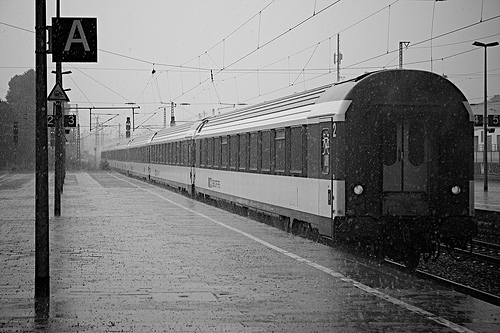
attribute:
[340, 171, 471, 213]
headlight — round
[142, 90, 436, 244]
train — domed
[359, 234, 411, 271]
rain — splashing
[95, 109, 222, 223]
train — domed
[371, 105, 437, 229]
doors — rear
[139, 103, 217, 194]
train — passing through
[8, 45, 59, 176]
trees — distant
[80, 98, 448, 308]
photo — black and white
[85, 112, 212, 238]
train — long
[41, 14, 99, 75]
letter a — suspended, on pole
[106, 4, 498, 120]
wiring — electrical, above train, numerous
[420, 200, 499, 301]
train tracks — black, metal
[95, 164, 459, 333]
line — painted, white, on platform, solid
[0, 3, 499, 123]
sky — grey, overcast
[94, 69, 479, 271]
train — pulled, along platform, large, in platform, moving, through city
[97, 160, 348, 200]
stripe — light, below windows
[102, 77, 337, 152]
lines — ridged, overhead, powering train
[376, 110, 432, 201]
doors — white, large, in front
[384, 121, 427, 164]
windows — oval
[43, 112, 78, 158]
numbers — large, on side, white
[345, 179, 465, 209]
light — white, on front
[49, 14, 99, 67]
sign — black, on post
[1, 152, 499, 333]
platform — wet